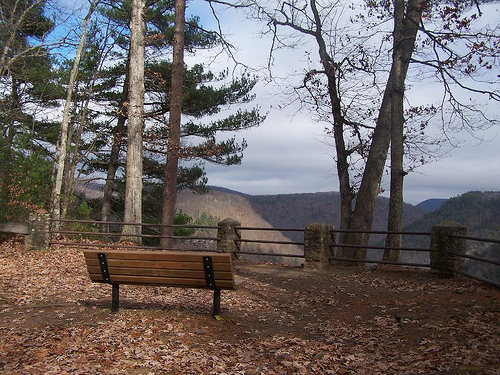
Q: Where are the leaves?
A: The ground.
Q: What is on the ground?
A: Bench.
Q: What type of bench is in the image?
A: Wood.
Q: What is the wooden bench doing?
A: Overlooking the mountains.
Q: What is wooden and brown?
A: Bench.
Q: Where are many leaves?
A: On the ground.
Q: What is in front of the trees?
A: A railing.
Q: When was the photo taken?
A: During daytime.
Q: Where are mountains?
A: In the distance.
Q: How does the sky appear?
A: Cloudy.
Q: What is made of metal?
A: The railings.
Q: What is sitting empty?
A: Bench.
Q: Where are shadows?
A: On the ground.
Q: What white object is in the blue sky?
A: Clouds.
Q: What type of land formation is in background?
A: Bluffs.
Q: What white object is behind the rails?
A: Tree trunk.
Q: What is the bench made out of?
A: Wood.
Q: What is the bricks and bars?
A: Guard rails.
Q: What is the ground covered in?
A: Leaves.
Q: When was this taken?
A: Daytime.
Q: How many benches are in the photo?
A: 1.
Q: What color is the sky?
A: Blue.